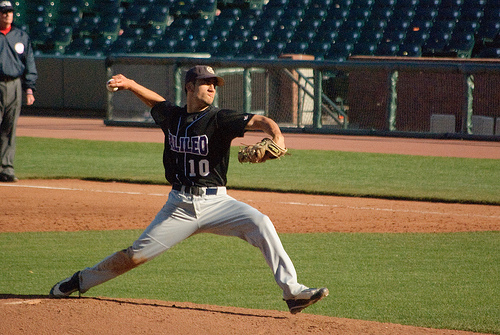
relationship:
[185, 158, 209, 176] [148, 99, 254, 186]
number on shirt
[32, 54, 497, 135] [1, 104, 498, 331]
fence around field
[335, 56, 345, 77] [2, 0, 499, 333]
chair in stadium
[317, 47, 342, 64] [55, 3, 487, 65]
chair in stadium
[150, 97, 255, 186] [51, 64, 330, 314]
shirt on man